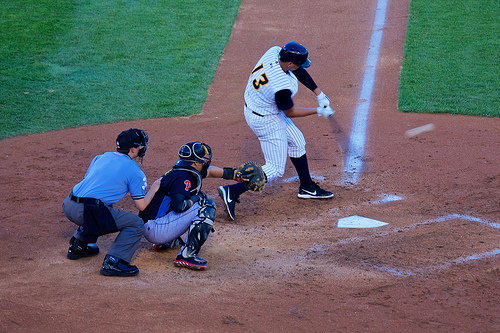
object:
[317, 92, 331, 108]
glove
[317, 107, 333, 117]
glove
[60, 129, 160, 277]
umpire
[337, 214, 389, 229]
plate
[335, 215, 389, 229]
diamond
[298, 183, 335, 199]
shoe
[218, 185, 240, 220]
shoe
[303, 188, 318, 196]
swish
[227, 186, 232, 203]
swish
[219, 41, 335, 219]
player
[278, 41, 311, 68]
helmet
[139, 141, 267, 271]
catcher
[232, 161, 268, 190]
mitt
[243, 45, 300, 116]
jersey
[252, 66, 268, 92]
thirteen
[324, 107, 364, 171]
bat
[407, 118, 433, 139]
ball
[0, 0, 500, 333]
territory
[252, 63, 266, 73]
number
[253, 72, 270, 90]
number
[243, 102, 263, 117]
belt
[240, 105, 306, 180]
pants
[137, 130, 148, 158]
shield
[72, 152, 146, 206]
shirt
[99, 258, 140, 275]
shoe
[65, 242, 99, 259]
shoe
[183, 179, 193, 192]
p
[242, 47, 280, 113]
back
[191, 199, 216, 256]
guard